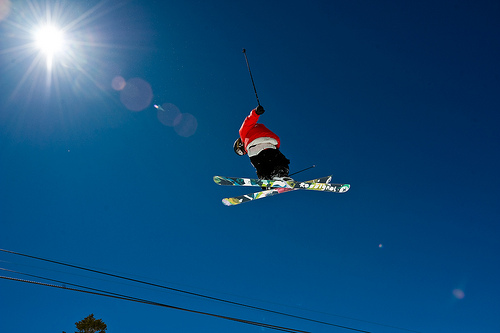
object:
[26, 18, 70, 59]
sun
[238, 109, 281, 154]
jacket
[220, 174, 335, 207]
skis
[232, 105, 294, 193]
person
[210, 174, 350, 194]
ski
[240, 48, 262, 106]
ski pole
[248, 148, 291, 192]
pants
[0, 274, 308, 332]
power lines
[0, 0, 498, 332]
sky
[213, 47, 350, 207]
tricks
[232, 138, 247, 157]
helmet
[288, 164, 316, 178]
ski poles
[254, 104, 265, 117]
glove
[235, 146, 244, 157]
goggles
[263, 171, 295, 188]
ski boots